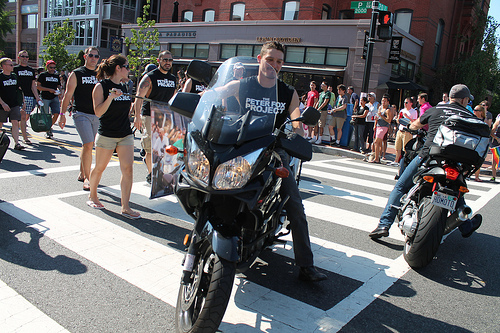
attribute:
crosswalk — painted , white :
[2, 155, 499, 330]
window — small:
[178, 8, 198, 22]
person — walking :
[57, 38, 99, 190]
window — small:
[293, 31, 357, 71]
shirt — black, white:
[236, 73, 294, 138]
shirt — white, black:
[415, 100, 476, 159]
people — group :
[52, 45, 352, 237]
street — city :
[11, 111, 498, 287]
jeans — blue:
[244, 181, 356, 269]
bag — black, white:
[429, 107, 493, 170]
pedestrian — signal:
[86, 53, 141, 221]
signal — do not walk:
[373, 9, 391, 37]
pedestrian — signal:
[59, 47, 109, 191]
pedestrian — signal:
[370, 95, 390, 162]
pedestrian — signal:
[393, 99, 420, 163]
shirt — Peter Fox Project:
[248, 89, 276, 110]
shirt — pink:
[419, 101, 429, 117]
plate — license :
[432, 187, 464, 212]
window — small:
[393, 6, 413, 33]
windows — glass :
[42, 8, 104, 40]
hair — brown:
[157, 49, 173, 61]